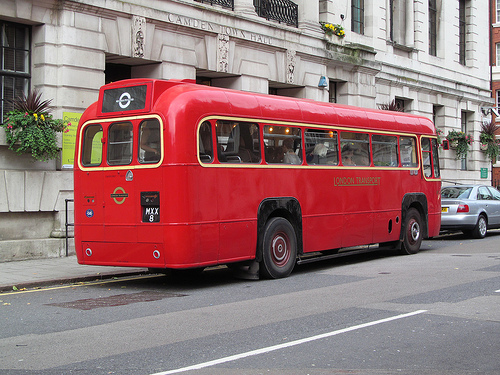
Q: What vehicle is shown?
A: A bus.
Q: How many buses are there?
A: 1.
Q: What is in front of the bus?
A: A car.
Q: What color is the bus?
A: Red.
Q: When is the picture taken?
A: Daytime.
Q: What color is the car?
A: Silver.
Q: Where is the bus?
A: On the street.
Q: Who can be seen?
A: Passengers on the bus.